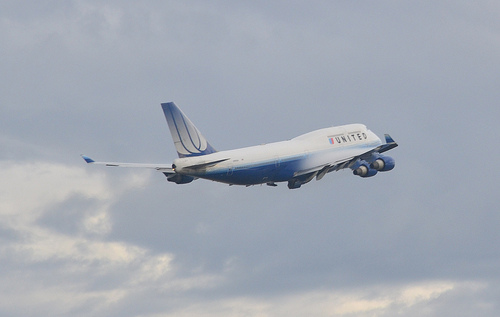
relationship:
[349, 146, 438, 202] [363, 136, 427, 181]
engines under wing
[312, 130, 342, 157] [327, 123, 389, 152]
symbol next to word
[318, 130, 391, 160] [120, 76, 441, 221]
windows on plane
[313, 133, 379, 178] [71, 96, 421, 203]
wing on plane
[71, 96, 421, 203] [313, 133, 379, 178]
plane has a wing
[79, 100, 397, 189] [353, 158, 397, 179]
plane has engines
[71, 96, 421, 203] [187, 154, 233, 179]
plane has a tail-wing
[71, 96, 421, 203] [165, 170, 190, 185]
plane has engines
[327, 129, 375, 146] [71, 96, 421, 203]
word on plane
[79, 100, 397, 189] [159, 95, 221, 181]
plane has a tail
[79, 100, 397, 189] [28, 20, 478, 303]
plane flying in sky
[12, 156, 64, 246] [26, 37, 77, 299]
clouds are in sky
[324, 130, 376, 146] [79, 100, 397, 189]
writing on plane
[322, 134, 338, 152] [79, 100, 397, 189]
symbol on plane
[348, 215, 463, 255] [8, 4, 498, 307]
section of sky